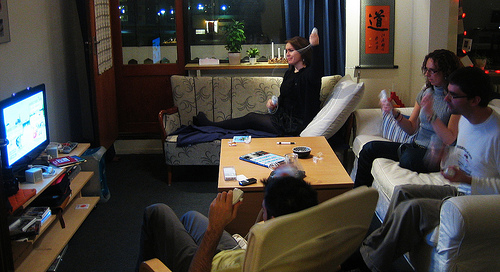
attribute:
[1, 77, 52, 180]
game — video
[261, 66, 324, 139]
sweater — black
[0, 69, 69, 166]
lcd — TV screen, small, flat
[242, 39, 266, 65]
plant — small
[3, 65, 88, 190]
computer — apple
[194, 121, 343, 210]
table — wood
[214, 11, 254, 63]
plant — tall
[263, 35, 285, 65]
candles — white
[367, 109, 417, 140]
pillow — white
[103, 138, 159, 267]
carpet — blue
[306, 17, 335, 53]
arm — raised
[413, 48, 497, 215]
person — sitting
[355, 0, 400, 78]
art — japanese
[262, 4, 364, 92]
curtain — black